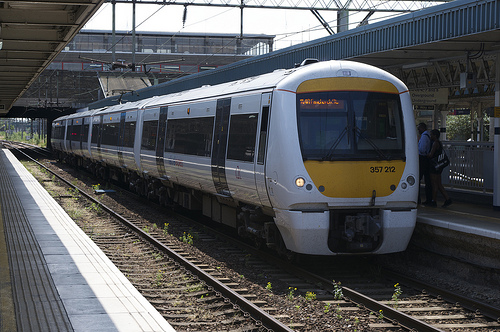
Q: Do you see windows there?
A: Yes, there are windows.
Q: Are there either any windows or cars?
A: Yes, there are windows.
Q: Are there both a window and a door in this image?
A: Yes, there are both a window and a door.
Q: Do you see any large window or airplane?
A: Yes, there are large windows.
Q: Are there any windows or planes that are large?
A: Yes, the windows are large.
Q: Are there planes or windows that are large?
A: Yes, the windows are large.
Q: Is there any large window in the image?
A: Yes, there are large windows.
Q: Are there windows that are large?
A: Yes, there are windows that are large.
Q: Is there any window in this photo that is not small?
A: Yes, there are large windows.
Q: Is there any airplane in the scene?
A: No, there are no airplanes.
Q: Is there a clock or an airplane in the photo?
A: No, there are no airplanes or clocks.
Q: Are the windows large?
A: Yes, the windows are large.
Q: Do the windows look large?
A: Yes, the windows are large.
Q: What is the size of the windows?
A: The windows are large.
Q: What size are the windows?
A: The windows are large.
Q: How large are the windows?
A: The windows are large.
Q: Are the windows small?
A: No, the windows are large.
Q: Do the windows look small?
A: No, the windows are large.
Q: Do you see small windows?
A: No, there are windows but they are large.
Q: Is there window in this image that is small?
A: No, there are windows but they are large.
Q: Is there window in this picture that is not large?
A: No, there are windows but they are large.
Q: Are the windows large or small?
A: The windows are large.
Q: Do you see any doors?
A: Yes, there are doors.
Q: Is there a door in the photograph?
A: Yes, there are doors.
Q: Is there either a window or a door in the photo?
A: Yes, there are doors.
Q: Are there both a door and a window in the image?
A: Yes, there are both a door and a window.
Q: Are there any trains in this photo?
A: Yes, there is a train.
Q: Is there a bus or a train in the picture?
A: Yes, there is a train.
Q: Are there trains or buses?
A: Yes, there is a train.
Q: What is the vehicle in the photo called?
A: The vehicle is a train.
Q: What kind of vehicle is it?
A: The vehicle is a train.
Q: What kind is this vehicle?
A: This is a train.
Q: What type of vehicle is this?
A: This is a train.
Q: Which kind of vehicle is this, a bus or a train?
A: This is a train.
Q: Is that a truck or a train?
A: That is a train.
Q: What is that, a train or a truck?
A: That is a train.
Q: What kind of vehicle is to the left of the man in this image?
A: The vehicle is a train.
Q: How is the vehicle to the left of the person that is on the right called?
A: The vehicle is a train.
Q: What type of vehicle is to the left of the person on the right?
A: The vehicle is a train.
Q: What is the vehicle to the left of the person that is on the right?
A: The vehicle is a train.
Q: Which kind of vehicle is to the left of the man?
A: The vehicle is a train.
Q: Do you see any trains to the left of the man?
A: Yes, there is a train to the left of the man.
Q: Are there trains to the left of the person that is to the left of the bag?
A: Yes, there is a train to the left of the man.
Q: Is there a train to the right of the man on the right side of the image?
A: No, the train is to the left of the man.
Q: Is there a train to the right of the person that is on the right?
A: No, the train is to the left of the man.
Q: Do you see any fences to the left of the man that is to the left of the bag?
A: No, there is a train to the left of the man.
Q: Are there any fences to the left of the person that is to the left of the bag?
A: No, there is a train to the left of the man.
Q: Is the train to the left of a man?
A: Yes, the train is to the left of a man.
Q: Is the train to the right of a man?
A: No, the train is to the left of a man.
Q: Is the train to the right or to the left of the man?
A: The train is to the left of the man.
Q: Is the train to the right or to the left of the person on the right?
A: The train is to the left of the man.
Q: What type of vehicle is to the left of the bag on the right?
A: The vehicle is a train.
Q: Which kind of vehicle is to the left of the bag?
A: The vehicle is a train.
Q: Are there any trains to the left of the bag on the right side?
A: Yes, there is a train to the left of the bag.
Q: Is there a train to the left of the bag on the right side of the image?
A: Yes, there is a train to the left of the bag.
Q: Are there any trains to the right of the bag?
A: No, the train is to the left of the bag.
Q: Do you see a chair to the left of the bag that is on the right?
A: No, there is a train to the left of the bag.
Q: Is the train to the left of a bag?
A: Yes, the train is to the left of a bag.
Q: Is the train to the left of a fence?
A: No, the train is to the left of a bag.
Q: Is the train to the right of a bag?
A: No, the train is to the left of a bag.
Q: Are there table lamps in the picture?
A: No, there are no table lamps.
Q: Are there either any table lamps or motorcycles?
A: No, there are no table lamps or motorcycles.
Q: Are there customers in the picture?
A: No, there are no customers.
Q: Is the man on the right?
A: Yes, the man is on the right of the image.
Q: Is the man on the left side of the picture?
A: No, the man is on the right of the image.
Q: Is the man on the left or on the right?
A: The man is on the right of the image.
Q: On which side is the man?
A: The man is on the right of the image.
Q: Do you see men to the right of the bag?
A: No, the man is to the left of the bag.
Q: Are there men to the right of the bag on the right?
A: No, the man is to the left of the bag.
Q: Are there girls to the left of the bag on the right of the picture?
A: No, there is a man to the left of the bag.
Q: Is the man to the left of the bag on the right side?
A: Yes, the man is to the left of the bag.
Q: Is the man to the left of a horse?
A: No, the man is to the left of the bag.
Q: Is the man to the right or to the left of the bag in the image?
A: The man is to the left of the bag.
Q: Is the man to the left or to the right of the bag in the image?
A: The man is to the left of the bag.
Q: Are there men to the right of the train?
A: Yes, there is a man to the right of the train.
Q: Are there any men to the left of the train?
A: No, the man is to the right of the train.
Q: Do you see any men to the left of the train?
A: No, the man is to the right of the train.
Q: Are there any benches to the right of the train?
A: No, there is a man to the right of the train.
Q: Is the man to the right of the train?
A: Yes, the man is to the right of the train.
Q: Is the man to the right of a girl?
A: No, the man is to the right of the train.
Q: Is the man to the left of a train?
A: No, the man is to the right of a train.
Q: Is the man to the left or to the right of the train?
A: The man is to the right of the train.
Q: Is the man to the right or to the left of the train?
A: The man is to the right of the train.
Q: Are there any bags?
A: Yes, there is a bag.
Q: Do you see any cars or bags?
A: Yes, there is a bag.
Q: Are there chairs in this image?
A: No, there are no chairs.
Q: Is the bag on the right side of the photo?
A: Yes, the bag is on the right of the image.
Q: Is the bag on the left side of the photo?
A: No, the bag is on the right of the image.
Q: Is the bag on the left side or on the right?
A: The bag is on the right of the image.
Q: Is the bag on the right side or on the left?
A: The bag is on the right of the image.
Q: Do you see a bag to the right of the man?
A: Yes, there is a bag to the right of the man.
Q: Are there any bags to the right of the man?
A: Yes, there is a bag to the right of the man.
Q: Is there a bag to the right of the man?
A: Yes, there is a bag to the right of the man.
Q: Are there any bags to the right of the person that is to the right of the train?
A: Yes, there is a bag to the right of the man.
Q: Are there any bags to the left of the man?
A: No, the bag is to the right of the man.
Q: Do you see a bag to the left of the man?
A: No, the bag is to the right of the man.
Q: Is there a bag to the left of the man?
A: No, the bag is to the right of the man.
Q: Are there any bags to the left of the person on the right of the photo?
A: No, the bag is to the right of the man.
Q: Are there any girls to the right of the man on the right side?
A: No, there is a bag to the right of the man.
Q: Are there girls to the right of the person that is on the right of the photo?
A: No, there is a bag to the right of the man.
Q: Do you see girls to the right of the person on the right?
A: No, there is a bag to the right of the man.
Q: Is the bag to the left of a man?
A: No, the bag is to the right of a man.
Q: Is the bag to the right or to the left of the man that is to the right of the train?
A: The bag is to the right of the man.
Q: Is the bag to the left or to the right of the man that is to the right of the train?
A: The bag is to the right of the man.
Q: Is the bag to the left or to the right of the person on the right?
A: The bag is to the right of the man.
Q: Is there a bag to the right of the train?
A: Yes, there is a bag to the right of the train.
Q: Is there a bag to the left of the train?
A: No, the bag is to the right of the train.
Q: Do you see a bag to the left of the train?
A: No, the bag is to the right of the train.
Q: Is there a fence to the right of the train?
A: No, there is a bag to the right of the train.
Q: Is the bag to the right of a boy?
A: No, the bag is to the right of a train.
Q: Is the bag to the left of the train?
A: No, the bag is to the right of the train.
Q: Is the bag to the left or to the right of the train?
A: The bag is to the right of the train.